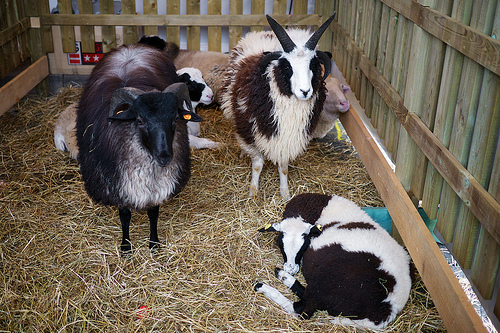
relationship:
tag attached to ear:
[176, 106, 200, 132] [167, 92, 197, 120]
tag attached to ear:
[180, 113, 194, 122] [175, 81, 201, 121]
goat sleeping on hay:
[252, 189, 413, 328] [0, 74, 449, 333]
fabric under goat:
[361, 201, 394, 233] [252, 189, 413, 328]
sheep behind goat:
[174, 50, 236, 111] [220, 11, 344, 202]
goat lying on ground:
[252, 189, 413, 328] [194, 183, 433, 330]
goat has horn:
[220, 11, 344, 202] [262, 13, 299, 50]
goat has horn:
[220, 11, 344, 202] [300, 11, 340, 50]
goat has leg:
[252, 189, 413, 328] [253, 278, 303, 324]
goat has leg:
[252, 189, 413, 328] [268, 262, 305, 298]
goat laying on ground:
[252, 189, 413, 328] [183, 202, 438, 331]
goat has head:
[252, 189, 413, 328] [254, 217, 320, 276]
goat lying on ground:
[252, 189, 413, 328] [188, 193, 454, 331]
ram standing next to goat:
[73, 33, 201, 254] [252, 189, 413, 328]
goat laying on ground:
[252, 189, 413, 328] [169, 173, 454, 330]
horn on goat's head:
[261, 8, 296, 52] [257, 12, 342, 105]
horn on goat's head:
[300, 11, 340, 50] [257, 12, 342, 105]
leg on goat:
[243, 154, 271, 201] [220, 11, 344, 202]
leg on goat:
[273, 161, 296, 205] [220, 11, 344, 202]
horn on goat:
[261, 8, 296, 52] [220, 11, 344, 202]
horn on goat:
[300, 11, 340, 50] [220, 11, 344, 202]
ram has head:
[73, 40, 200, 255] [105, 79, 197, 163]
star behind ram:
[79, 51, 91, 64] [73, 40, 200, 255]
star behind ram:
[91, 51, 102, 61] [73, 40, 200, 255]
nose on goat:
[300, 88, 311, 98] [220, 11, 344, 202]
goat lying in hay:
[252, 189, 413, 328] [194, 174, 444, 331]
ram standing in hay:
[73, 40, 200, 255] [17, 160, 258, 321]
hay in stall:
[7, 247, 223, 331] [10, 5, 496, 327]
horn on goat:
[261, 8, 296, 52] [220, 11, 340, 202]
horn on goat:
[300, 11, 340, 50] [220, 11, 340, 202]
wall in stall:
[400, 12, 495, 204] [10, 5, 496, 327]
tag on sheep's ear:
[259, 218, 270, 232] [250, 214, 282, 241]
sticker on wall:
[66, 37, 112, 65] [25, 2, 138, 77]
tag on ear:
[180, 113, 194, 122] [179, 108, 203, 123]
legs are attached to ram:
[111, 202, 172, 256] [75, 32, 208, 239]